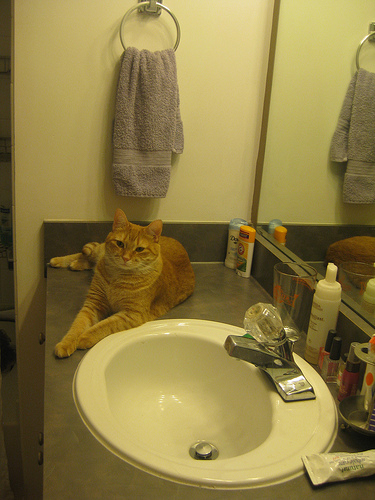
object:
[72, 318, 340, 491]
sink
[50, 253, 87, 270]
leg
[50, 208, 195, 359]
cat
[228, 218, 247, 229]
deodorant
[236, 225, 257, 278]
deodorant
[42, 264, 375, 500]
counter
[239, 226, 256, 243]
cap deodorant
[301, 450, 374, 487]
toothpaste tube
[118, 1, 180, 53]
towel ring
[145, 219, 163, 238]
ear